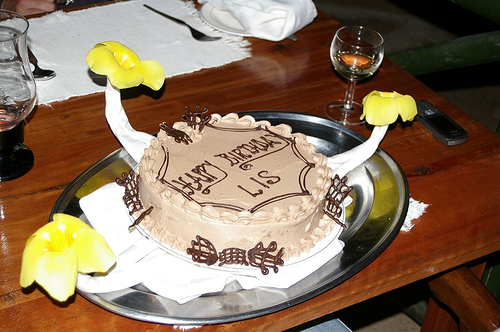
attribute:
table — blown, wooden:
[438, 173, 496, 213]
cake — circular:
[157, 120, 361, 205]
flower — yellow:
[75, 34, 180, 194]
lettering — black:
[174, 128, 301, 201]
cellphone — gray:
[404, 97, 489, 154]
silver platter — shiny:
[131, 297, 236, 325]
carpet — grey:
[364, 310, 416, 330]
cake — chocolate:
[115, 99, 362, 276]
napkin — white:
[215, 0, 329, 47]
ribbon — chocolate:
[138, 110, 335, 223]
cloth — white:
[15, 0, 250, 105]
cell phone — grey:
[400, 93, 471, 148]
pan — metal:
[41, 103, 415, 330]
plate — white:
[197, 1, 255, 39]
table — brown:
[6, 4, 498, 324]